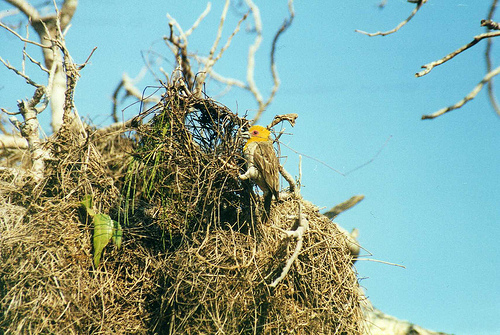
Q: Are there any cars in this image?
A: No, there are no cars.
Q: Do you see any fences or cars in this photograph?
A: No, there are no cars or fences.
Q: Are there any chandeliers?
A: No, there are no chandeliers.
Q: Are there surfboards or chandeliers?
A: No, there are no chandeliers or surfboards.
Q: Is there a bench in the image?
A: Yes, there is a bench.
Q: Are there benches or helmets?
A: Yes, there is a bench.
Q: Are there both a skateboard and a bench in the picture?
A: No, there is a bench but no skateboards.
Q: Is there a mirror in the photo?
A: No, there are no mirrors.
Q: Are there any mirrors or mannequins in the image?
A: No, there are no mirrors or mannequins.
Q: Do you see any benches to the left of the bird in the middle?
A: Yes, there is a bench to the left of the bird.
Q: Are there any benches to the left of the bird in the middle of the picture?
A: Yes, there is a bench to the left of the bird.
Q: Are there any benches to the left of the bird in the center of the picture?
A: Yes, there is a bench to the left of the bird.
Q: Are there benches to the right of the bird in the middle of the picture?
A: No, the bench is to the left of the bird.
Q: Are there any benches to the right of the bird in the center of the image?
A: No, the bench is to the left of the bird.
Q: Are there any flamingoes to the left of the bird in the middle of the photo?
A: No, there is a bench to the left of the bird.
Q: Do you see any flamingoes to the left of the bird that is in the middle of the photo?
A: No, there is a bench to the left of the bird.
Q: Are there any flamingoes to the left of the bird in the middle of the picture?
A: No, there is a bench to the left of the bird.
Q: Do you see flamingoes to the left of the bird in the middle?
A: No, there is a bench to the left of the bird.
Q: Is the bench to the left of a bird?
A: Yes, the bench is to the left of a bird.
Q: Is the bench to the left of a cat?
A: No, the bench is to the left of a bird.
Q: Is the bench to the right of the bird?
A: No, the bench is to the left of the bird.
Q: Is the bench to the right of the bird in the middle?
A: No, the bench is to the left of the bird.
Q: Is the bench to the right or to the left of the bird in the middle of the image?
A: The bench is to the left of the bird.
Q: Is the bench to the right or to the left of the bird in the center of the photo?
A: The bench is to the left of the bird.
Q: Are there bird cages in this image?
A: No, there are no bird cages.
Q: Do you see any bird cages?
A: No, there are no bird cages.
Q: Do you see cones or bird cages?
A: No, there are no bird cages or cones.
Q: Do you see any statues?
A: No, there are no statues.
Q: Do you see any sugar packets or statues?
A: No, there are no statues or sugar packets.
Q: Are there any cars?
A: No, there are no cars.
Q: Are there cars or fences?
A: No, there are no cars or fences.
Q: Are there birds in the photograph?
A: Yes, there is a bird.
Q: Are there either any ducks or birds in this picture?
A: Yes, there is a bird.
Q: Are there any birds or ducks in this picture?
A: Yes, there is a bird.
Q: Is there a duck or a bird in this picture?
A: Yes, there is a bird.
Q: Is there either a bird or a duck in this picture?
A: Yes, there is a bird.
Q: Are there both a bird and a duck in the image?
A: No, there is a bird but no ducks.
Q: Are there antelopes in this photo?
A: No, there are no antelopes.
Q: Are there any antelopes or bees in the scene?
A: No, there are no antelopes or bees.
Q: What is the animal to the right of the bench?
A: The animal is a bird.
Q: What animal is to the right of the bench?
A: The animal is a bird.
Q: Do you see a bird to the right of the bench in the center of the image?
A: Yes, there is a bird to the right of the bench.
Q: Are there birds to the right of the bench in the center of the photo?
A: Yes, there is a bird to the right of the bench.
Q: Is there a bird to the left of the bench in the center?
A: No, the bird is to the right of the bench.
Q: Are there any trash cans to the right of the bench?
A: No, there is a bird to the right of the bench.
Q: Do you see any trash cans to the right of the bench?
A: No, there is a bird to the right of the bench.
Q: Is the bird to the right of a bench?
A: Yes, the bird is to the right of a bench.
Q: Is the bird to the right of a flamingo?
A: No, the bird is to the right of a bench.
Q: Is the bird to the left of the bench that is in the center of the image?
A: No, the bird is to the right of the bench.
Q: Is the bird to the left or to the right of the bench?
A: The bird is to the right of the bench.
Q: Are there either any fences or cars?
A: No, there are no cars or fences.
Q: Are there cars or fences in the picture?
A: No, there are no cars or fences.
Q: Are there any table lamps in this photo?
A: No, there are no table lamps.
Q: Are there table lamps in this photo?
A: No, there are no table lamps.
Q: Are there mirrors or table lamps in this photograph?
A: No, there are no table lamps or mirrors.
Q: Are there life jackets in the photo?
A: No, there are no life jackets.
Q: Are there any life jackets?
A: No, there are no life jackets.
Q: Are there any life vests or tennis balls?
A: No, there are no life vests or tennis balls.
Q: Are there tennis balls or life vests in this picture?
A: No, there are no life vests or tennis balls.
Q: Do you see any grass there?
A: Yes, there is grass.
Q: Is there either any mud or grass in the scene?
A: Yes, there is grass.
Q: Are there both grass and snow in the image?
A: No, there is grass but no snow.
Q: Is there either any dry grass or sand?
A: Yes, there is dry grass.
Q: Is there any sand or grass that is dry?
A: Yes, the grass is dry.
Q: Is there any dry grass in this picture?
A: Yes, there is dry grass.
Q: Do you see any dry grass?
A: Yes, there is dry grass.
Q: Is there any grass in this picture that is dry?
A: Yes, there is grass that is dry.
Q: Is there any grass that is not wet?
A: Yes, there is dry grass.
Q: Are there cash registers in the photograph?
A: No, there are no cash registers.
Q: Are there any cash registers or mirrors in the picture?
A: No, there are no cash registers or mirrors.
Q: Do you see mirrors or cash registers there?
A: No, there are no cash registers or mirrors.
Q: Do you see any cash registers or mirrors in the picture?
A: No, there are no cash registers or mirrors.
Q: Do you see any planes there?
A: No, there are no planes.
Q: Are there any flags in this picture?
A: No, there are no flags.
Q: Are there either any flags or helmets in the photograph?
A: No, there are no flags or helmets.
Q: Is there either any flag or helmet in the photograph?
A: No, there are no flags or helmets.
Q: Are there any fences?
A: No, there are no fences.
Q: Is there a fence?
A: No, there are no fences.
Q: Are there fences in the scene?
A: No, there are no fences.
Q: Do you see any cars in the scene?
A: No, there are no cars.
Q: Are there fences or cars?
A: No, there are no cars or fences.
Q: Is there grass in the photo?
A: Yes, there is grass.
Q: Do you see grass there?
A: Yes, there is grass.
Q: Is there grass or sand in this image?
A: Yes, there is grass.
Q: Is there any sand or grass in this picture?
A: Yes, there is grass.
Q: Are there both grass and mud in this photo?
A: No, there is grass but no mud.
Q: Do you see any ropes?
A: No, there are no ropes.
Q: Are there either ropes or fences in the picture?
A: No, there are no ropes or fences.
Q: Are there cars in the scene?
A: No, there are no cars.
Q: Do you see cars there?
A: No, there are no cars.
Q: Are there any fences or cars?
A: No, there are no cars or fences.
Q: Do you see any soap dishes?
A: No, there are no soap dishes.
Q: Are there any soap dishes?
A: No, there are no soap dishes.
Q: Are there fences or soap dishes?
A: No, there are no soap dishes or fences.